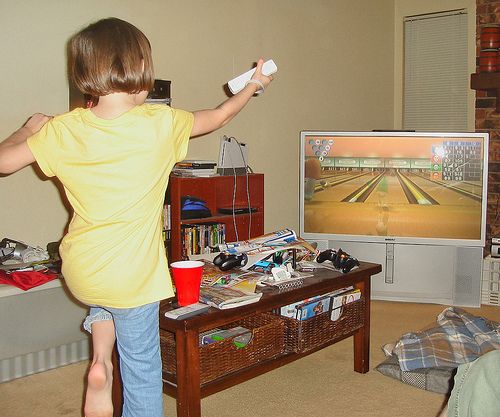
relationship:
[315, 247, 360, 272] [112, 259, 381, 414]
controller on table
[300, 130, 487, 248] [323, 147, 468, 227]
tv has game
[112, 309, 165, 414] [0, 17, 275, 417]
pant leg on child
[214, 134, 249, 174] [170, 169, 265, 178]
game system on shelf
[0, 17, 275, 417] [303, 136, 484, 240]
child playing game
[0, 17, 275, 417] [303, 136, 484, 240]
child plays game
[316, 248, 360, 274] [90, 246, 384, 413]
controller on table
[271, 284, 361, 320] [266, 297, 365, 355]
cases in basket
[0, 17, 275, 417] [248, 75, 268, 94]
child wearing wristband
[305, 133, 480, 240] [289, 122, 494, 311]
game on tv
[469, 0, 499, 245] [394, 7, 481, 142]
brick wall next to window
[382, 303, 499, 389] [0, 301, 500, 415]
blanket on carpet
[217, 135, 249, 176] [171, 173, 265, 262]
game system on bookshelf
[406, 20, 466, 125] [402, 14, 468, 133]
blinds beside blinds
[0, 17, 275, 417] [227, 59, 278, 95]
child holding control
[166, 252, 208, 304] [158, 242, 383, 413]
cup on table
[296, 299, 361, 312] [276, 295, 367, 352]
movies in basket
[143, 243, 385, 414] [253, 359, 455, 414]
coffee table on carpet